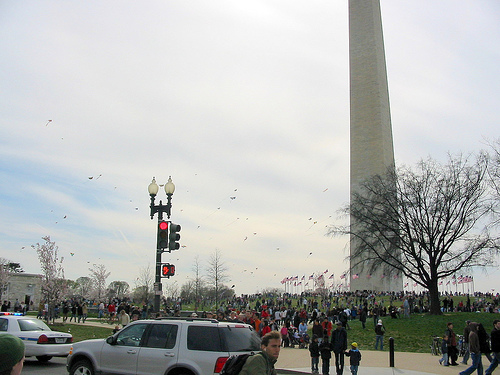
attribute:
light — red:
[156, 218, 170, 233]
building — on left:
[1, 268, 50, 313]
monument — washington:
[345, 1, 413, 296]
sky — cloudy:
[8, 164, 96, 233]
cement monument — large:
[342, 0, 407, 295]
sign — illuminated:
[152, 216, 192, 306]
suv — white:
[63, 319, 270, 374]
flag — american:
[451, 272, 456, 287]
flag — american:
[347, 270, 358, 281]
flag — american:
[325, 272, 339, 284]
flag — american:
[313, 272, 325, 282]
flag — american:
[303, 271, 313, 281]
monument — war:
[334, 50, 401, 177]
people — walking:
[52, 297, 90, 326]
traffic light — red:
[157, 218, 169, 248]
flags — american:
[274, 269, 480, 291]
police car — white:
[3, 307, 74, 366]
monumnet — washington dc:
[339, 0, 413, 308]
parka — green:
[234, 352, 276, 372]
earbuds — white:
[262, 346, 274, 361]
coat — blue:
[343, 349, 363, 365]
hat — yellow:
[348, 339, 359, 349]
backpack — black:
[217, 352, 250, 372]